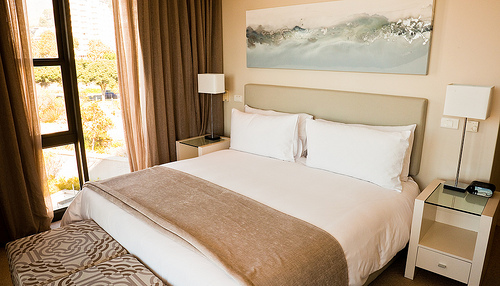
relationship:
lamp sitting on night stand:
[197, 69, 224, 141] [173, 135, 229, 160]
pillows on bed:
[301, 115, 412, 193] [76, 79, 429, 284]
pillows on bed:
[302, 115, 416, 191] [76, 79, 429, 284]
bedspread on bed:
[96, 164, 279, 282] [76, 79, 429, 284]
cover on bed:
[195, 149, 351, 205] [76, 79, 429, 284]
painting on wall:
[243, 7, 431, 74] [223, 0, 469, 93]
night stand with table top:
[176, 130, 230, 156] [184, 135, 220, 145]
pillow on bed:
[228, 104, 300, 164] [76, 79, 429, 284]